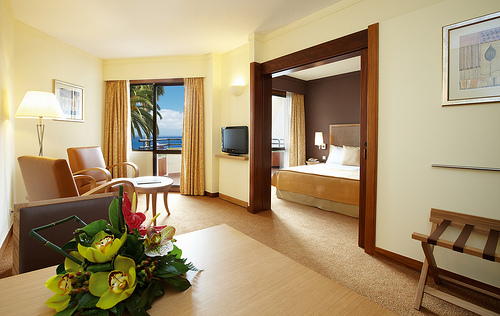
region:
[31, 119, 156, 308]
the flower is yellow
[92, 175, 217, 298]
the flower is yellow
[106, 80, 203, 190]
sliding door with a palm tree and beach view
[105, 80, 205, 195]
curtains hanging over sliding door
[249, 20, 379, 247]
bedroom entrance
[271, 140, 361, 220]
large bed with two white pillows on it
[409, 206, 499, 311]
stand made of wood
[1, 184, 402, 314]
green plant on a wooden table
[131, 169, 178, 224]
round wooden table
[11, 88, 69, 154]
lit white lamp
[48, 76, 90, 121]
art hanging from the wall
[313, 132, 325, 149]
white lamp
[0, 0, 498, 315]
hotel room near ocean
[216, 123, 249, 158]
black flatscreen tv on wall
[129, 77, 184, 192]
balcony overlooking ocean and palm tree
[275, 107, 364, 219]
big bed in hotel room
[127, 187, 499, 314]
tan fuzzy carpet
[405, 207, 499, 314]
brown wooden luggage rack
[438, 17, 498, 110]
picture with leaf on wall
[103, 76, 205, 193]
yellow patterned curtains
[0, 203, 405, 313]
flowers on wooden table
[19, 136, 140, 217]
brown chairs in background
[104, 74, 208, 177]
window with curtains open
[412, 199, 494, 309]
wood rack to put clothes on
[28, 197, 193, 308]
plastic flower arrangement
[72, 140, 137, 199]
wood chair with leather cushions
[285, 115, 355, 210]
queen size bed with white cover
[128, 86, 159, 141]
palm tree outside of window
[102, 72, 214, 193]
window with beige curtains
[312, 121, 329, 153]
lamp on the wall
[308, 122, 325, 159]
lamp next to bed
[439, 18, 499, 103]
art displayed on the wall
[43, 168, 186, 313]
the flower